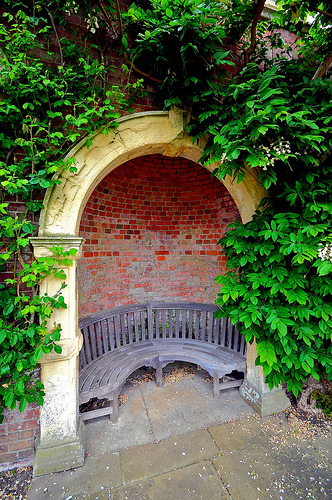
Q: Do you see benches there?
A: Yes, there is a bench.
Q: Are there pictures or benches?
A: Yes, there is a bench.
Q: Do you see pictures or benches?
A: Yes, there is a bench.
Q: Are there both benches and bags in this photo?
A: No, there is a bench but no bags.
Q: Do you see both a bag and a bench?
A: No, there is a bench but no bags.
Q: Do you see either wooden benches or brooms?
A: Yes, there is a wood bench.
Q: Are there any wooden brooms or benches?
A: Yes, there is a wood bench.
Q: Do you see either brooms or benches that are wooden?
A: Yes, the bench is wooden.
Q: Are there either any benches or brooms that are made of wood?
A: Yes, the bench is made of wood.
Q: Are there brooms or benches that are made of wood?
A: Yes, the bench is made of wood.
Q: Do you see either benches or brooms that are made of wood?
A: Yes, the bench is made of wood.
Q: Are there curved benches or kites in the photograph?
A: Yes, there is a curved bench.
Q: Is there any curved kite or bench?
A: Yes, there is a curved bench.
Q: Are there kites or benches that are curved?
A: Yes, the bench is curved.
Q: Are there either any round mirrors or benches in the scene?
A: Yes, there is a round bench.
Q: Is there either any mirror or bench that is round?
A: Yes, the bench is round.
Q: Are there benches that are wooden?
A: Yes, there is a wood bench.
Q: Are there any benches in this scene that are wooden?
A: Yes, there is a bench that is wooden.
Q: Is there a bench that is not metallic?
A: Yes, there is a wooden bench.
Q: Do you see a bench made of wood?
A: Yes, there is a bench that is made of wood.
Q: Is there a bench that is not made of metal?
A: Yes, there is a bench that is made of wood.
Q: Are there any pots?
A: No, there are no pots.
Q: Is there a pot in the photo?
A: No, there are no pots.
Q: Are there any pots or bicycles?
A: No, there are no pots or bicycles.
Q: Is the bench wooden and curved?
A: Yes, the bench is wooden and curved.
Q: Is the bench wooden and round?
A: Yes, the bench is wooden and round.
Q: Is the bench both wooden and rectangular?
A: No, the bench is wooden but round.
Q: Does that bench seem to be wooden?
A: Yes, the bench is wooden.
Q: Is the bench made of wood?
A: Yes, the bench is made of wood.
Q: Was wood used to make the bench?
A: Yes, the bench is made of wood.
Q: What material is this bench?
A: The bench is made of wood.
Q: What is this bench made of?
A: The bench is made of wood.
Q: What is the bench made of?
A: The bench is made of wood.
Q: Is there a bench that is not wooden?
A: No, there is a bench but it is wooden.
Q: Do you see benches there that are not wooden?
A: No, there is a bench but it is wooden.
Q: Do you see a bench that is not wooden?
A: No, there is a bench but it is wooden.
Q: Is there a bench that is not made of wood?
A: No, there is a bench but it is made of wood.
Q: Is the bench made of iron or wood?
A: The bench is made of wood.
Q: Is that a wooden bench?
A: Yes, that is a wooden bench.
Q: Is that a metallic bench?
A: No, that is a wooden bench.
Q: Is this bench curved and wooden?
A: Yes, the bench is curved and wooden.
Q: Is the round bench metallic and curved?
A: No, the bench is curved but wooden.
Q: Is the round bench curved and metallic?
A: No, the bench is curved but wooden.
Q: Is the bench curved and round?
A: Yes, the bench is curved and round.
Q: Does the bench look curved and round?
A: Yes, the bench is curved and round.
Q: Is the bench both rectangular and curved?
A: No, the bench is curved but round.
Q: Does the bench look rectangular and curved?
A: No, the bench is curved but round.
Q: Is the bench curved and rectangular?
A: No, the bench is curved but round.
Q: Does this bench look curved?
A: Yes, the bench is curved.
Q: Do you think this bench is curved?
A: Yes, the bench is curved.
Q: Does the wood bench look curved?
A: Yes, the bench is curved.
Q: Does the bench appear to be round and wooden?
A: Yes, the bench is round and wooden.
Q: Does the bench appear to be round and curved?
A: Yes, the bench is round and curved.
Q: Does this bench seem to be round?
A: Yes, the bench is round.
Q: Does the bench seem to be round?
A: Yes, the bench is round.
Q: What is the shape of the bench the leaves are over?
A: The bench is round.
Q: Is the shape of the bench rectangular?
A: No, the bench is round.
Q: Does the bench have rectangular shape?
A: No, the bench is round.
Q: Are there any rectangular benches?
A: No, there is a bench but it is round.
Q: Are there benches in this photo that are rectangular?
A: No, there is a bench but it is round.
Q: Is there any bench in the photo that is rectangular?
A: No, there is a bench but it is round.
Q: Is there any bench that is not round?
A: No, there is a bench but it is round.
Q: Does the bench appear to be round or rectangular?
A: The bench is round.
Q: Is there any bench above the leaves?
A: Yes, there is a bench above the leaves.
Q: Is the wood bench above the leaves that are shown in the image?
A: Yes, the bench is above the leaves.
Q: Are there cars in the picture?
A: No, there are no cars.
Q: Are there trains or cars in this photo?
A: No, there are no cars or trains.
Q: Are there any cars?
A: No, there are no cars.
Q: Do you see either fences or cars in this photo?
A: No, there are no cars or fences.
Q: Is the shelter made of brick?
A: Yes, the shelter is made of brick.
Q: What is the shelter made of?
A: The shelter is made of brick.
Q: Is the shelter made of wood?
A: No, the shelter is made of brick.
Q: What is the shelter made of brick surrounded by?
A: The shelter is surrounded by the leaves.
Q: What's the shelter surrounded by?
A: The shelter is surrounded by the leaves.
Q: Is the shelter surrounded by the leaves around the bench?
A: Yes, the shelter is surrounded by the leaves.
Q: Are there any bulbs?
A: No, there are no bulbs.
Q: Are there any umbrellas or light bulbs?
A: No, there are no light bulbs or umbrellas.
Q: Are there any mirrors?
A: No, there are no mirrors.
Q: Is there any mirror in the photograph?
A: No, there are no mirrors.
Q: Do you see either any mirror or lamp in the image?
A: No, there are no mirrors or lamps.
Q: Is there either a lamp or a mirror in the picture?
A: No, there are no mirrors or lamps.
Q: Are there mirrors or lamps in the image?
A: No, there are no mirrors or lamps.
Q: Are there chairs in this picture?
A: No, there are no chairs.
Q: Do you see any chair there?
A: No, there are no chairs.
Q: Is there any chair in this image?
A: No, there are no chairs.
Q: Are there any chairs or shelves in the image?
A: No, there are no chairs or shelves.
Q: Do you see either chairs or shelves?
A: No, there are no chairs or shelves.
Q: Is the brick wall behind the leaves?
A: Yes, the wall is behind the leaves.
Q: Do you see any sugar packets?
A: No, there are no sugar packets.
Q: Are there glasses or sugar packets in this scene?
A: No, there are no sugar packets or glasses.